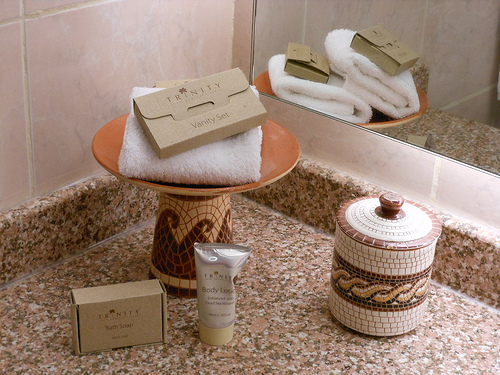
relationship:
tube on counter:
[192, 232, 251, 346] [1, 157, 498, 373]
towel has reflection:
[120, 82, 265, 185] [266, 21, 421, 124]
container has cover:
[327, 190, 443, 339] [335, 189, 443, 251]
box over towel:
[128, 65, 268, 160] [120, 82, 265, 185]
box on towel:
[128, 65, 268, 160] [120, 82, 265, 185]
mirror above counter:
[252, 4, 500, 178] [1, 157, 498, 373]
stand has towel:
[90, 112, 300, 299] [120, 82, 265, 185]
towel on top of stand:
[120, 82, 265, 185] [90, 112, 300, 299]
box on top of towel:
[128, 65, 268, 160] [120, 82, 265, 185]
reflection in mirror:
[266, 21, 421, 124] [252, 4, 500, 178]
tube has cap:
[192, 232, 251, 346] [198, 321, 237, 346]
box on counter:
[66, 278, 171, 356] [1, 157, 498, 373]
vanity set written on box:
[187, 112, 233, 130] [128, 65, 268, 160]